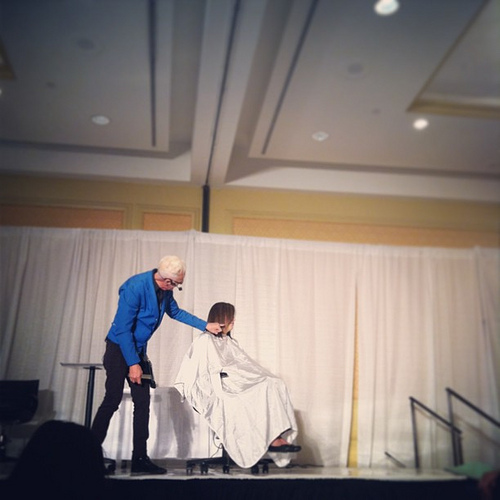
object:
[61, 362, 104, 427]
table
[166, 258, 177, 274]
hair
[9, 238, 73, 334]
white curtains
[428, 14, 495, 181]
ceiling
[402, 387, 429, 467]
rails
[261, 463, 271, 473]
wheel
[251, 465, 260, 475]
wheel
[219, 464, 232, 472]
wheel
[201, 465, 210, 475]
wheel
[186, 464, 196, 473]
wheel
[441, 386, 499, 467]
railing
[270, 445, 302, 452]
black shoes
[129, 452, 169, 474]
black shoes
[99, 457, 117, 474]
black shoes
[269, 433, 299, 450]
feet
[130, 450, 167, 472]
feet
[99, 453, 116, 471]
feet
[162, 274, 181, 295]
headset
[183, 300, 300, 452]
woman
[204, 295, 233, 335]
hair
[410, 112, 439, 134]
lights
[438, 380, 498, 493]
stair case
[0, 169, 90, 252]
trim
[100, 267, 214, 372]
sweater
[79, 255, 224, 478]
barber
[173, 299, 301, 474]
woman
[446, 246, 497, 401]
drapes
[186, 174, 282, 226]
wall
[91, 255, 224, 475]
hairstylist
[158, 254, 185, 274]
blonde hair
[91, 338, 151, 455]
slacks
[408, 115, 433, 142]
light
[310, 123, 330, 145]
light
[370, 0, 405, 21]
light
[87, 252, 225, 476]
man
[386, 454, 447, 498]
stage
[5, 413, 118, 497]
audience member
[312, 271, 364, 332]
white drapes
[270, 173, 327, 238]
wall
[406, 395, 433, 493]
stairs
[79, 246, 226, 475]
man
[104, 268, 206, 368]
cardigan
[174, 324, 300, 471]
cape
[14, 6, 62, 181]
ceiling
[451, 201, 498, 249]
wall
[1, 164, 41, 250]
wall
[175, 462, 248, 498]
stage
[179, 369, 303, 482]
chair